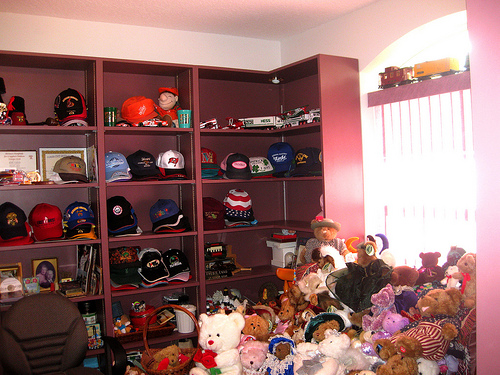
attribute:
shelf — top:
[197, 117, 327, 138]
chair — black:
[11, 274, 118, 366]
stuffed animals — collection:
[233, 232, 466, 374]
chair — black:
[1, 291, 93, 370]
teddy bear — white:
[186, 310, 247, 374]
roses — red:
[193, 347, 220, 372]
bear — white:
[185, 304, 247, 374]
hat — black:
[130, 147, 157, 179]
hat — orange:
[117, 84, 162, 126]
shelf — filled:
[1, 220, 311, 253]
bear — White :
[188, 309, 245, 373]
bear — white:
[384, 286, 459, 373]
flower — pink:
[313, 211, 327, 222]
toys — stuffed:
[310, 246, 454, 353]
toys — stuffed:
[194, 293, 299, 362]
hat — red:
[28, 203, 63, 238]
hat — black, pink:
[243, 153, 278, 188]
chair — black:
[1, 297, 93, 368]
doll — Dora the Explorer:
[299, 320, 347, 332]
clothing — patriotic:
[411, 315, 454, 357]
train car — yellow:
[410, 53, 459, 81]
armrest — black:
[92, 335, 128, 373]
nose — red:
[206, 338, 216, 345]